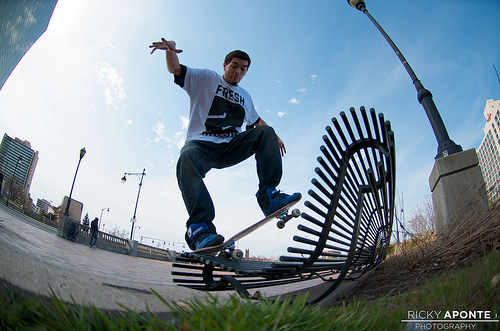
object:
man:
[146, 37, 303, 249]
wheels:
[277, 208, 300, 229]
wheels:
[219, 250, 242, 261]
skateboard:
[191, 200, 302, 260]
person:
[88, 217, 99, 250]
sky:
[0, 0, 499, 258]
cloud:
[46, 55, 126, 113]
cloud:
[277, 110, 286, 118]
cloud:
[288, 96, 298, 103]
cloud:
[153, 118, 170, 144]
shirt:
[174, 64, 261, 144]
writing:
[216, 84, 245, 106]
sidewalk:
[0, 207, 388, 313]